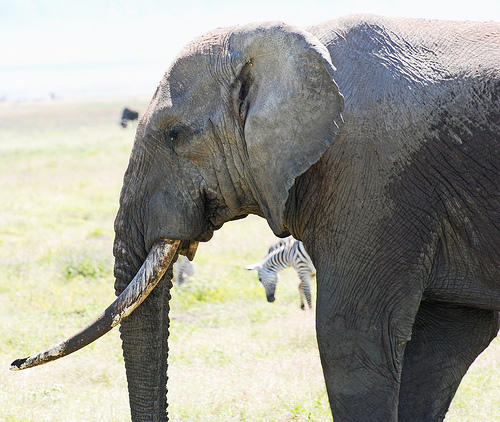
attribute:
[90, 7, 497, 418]
skin — wrinkled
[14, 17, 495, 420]
elephant — standing, wild, old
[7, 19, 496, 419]
elephnat — huge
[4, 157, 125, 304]
grass — green, sparse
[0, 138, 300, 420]
grass — brown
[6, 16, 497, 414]
animal — African, wild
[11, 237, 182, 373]
tusk — white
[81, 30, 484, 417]
elephant — gray, large, grey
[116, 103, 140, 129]
buffalo — distant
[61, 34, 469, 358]
elephant — close up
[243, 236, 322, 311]
zebra — black, white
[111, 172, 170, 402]
tusk — dirty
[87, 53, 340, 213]
elephant — grey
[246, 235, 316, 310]
zebra — white, black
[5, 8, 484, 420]
animals — wild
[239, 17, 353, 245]
ears — small